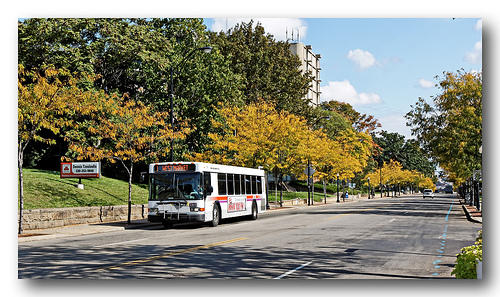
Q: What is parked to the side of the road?
A: A bus.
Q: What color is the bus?
A: White with some red.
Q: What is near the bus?
A: Trees.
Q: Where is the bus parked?
A: On the side of the road.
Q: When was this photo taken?
A: During the day.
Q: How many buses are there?
A: 1.